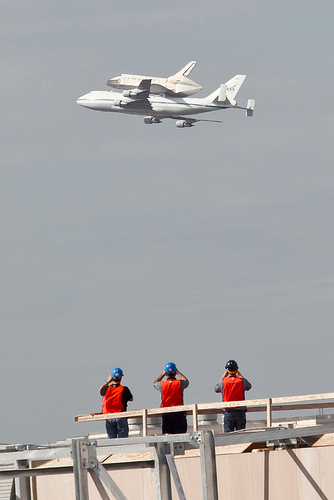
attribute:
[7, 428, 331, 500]
surface — wood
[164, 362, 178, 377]
helmet — blue, hardhat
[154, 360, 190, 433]
man — working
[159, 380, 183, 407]
shirt — bright, red, orange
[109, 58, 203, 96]
space shuttle — white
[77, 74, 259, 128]
jumbo jet — white, big, flying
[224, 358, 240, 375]
hardhat — black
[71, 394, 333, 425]
railing — thin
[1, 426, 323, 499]
structure — metal, long, large, scaffle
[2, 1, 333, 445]
sky — dreary, pale gray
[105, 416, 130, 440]
jeans — blue